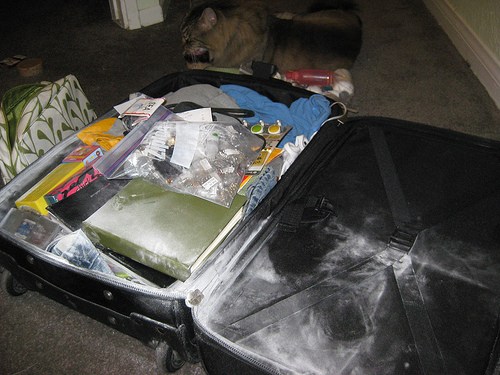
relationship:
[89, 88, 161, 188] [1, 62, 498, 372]
item inside suitcase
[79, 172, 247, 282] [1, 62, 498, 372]
item inside suitcase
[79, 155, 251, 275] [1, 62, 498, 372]
item inside suitcase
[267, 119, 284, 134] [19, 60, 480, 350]
item inside suitcase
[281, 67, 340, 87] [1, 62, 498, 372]
item inside suitcase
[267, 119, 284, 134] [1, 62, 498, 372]
item inside suitcase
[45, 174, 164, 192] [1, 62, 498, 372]
item inside suitcase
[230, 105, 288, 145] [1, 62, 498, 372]
item inside suitcase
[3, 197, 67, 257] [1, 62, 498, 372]
item inside suitcase